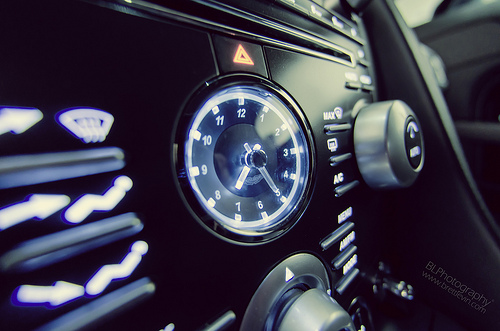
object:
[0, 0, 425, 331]
cd player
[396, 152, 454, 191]
ground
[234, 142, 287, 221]
7:25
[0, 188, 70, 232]
slice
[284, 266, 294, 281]
button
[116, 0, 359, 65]
cd slot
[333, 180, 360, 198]
ac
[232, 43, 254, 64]
light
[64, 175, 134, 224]
lights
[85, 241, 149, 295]
lights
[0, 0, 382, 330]
dash board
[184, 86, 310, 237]
clock face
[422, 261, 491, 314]
information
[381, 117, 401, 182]
edge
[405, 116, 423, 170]
button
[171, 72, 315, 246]
clock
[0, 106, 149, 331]
vent controls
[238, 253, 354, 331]
controls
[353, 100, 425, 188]
controls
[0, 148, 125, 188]
button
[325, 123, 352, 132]
button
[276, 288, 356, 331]
knob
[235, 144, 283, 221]
part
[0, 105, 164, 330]
a/c button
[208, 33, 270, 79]
button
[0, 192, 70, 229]
arrow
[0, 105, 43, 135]
arrow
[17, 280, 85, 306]
arrow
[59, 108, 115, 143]
start button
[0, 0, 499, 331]
car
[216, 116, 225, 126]
numbers